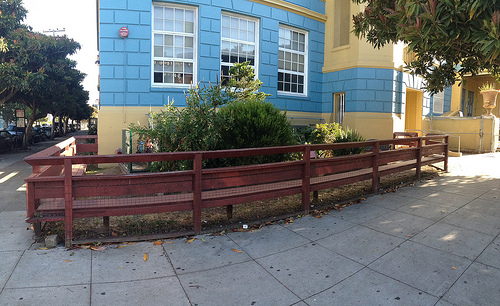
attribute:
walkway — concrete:
[0, 150, 497, 302]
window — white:
[157, 6, 192, 86]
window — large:
[212, 4, 264, 93]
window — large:
[153, 3, 196, 86]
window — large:
[219, 10, 255, 92]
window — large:
[278, 25, 307, 90]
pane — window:
[278, 72, 284, 81]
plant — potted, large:
[302, 115, 374, 166]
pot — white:
[474, 83, 493, 115]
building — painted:
[91, 2, 499, 170]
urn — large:
[470, 80, 498, 117]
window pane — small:
[155, 33, 163, 45]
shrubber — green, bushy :
[132, 79, 298, 167]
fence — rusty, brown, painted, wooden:
[26, 131, 454, 237]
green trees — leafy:
[382, 7, 498, 64]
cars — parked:
[2, 120, 74, 151]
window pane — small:
[291, 52, 299, 70]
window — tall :
[145, 11, 193, 88]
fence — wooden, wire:
[368, 120, 460, 173]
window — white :
[275, 20, 310, 101]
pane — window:
[163, 60, 175, 73]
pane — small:
[154, 37, 161, 59]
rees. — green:
[3, 10, 110, 178]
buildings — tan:
[84, 5, 498, 177]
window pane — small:
[165, 33, 174, 43]